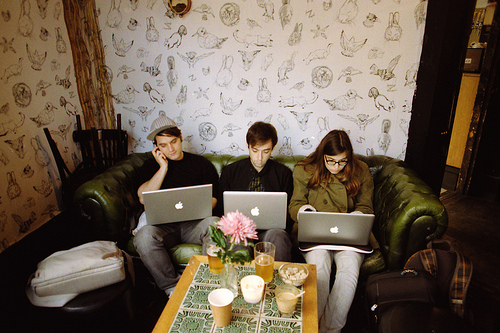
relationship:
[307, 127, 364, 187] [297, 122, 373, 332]
head of girl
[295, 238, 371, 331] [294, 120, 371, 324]
pants on girl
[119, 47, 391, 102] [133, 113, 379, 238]
wall behind people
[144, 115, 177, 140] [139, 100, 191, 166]
cap on head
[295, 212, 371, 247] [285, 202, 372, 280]
lap on lap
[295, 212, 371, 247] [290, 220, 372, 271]
lap on lap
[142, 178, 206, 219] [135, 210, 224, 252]
macbook on lap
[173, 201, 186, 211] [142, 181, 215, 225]
apple on macbook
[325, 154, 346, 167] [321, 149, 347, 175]
glasses on face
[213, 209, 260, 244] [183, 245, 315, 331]
flower on table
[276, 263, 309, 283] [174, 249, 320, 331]
bowl on table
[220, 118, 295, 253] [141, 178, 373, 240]
man on laptops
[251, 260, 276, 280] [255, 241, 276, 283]
liquid in glass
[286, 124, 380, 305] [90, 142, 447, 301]
person on couch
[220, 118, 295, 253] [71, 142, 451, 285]
man on the couch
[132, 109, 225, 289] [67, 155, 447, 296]
man on the couch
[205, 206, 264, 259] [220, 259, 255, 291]
flower in the vase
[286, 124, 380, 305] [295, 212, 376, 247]
person using  the macbook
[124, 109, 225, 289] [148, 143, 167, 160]
man on the phone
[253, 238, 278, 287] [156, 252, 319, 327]
glass on table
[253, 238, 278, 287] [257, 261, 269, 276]
glass of liquid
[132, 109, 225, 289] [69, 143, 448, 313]
man sitting couch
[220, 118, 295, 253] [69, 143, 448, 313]
man sitting couch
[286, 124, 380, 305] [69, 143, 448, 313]
person sitting couch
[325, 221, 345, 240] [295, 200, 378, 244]
apple on front of computer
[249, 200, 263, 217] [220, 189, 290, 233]
apple on front of computer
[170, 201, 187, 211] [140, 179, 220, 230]
apple on front of computer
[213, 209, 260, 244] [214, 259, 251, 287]
flower in vase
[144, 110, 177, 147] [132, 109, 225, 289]
cap on man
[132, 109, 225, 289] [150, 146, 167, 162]
man on phone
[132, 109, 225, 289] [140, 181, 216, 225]
man holding lap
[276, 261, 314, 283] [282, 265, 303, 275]
bowl of chips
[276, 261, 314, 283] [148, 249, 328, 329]
bowl on table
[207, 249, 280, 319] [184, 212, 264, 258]
vase with flower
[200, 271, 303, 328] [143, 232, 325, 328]
cup on table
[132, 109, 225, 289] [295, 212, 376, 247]
man with macbook